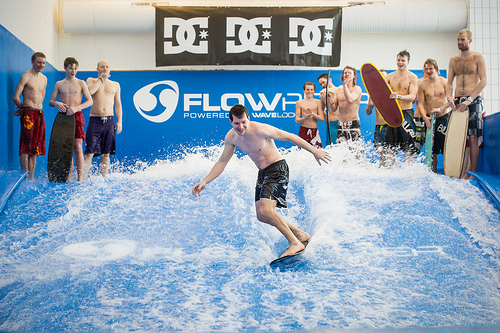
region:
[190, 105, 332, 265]
A person surfing indoors.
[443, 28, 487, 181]
A man with a tan surfboard.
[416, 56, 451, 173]
A person with a green surfboard.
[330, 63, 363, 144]
A male in black and white shorts.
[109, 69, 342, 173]
A blue and white sign.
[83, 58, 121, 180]
A guy wearing blue shorts.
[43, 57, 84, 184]
A kid with a black surfboard.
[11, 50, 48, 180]
A person wearing red shorts.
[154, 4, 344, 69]
A black and white sign.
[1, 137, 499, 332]
A indoor surf simulator.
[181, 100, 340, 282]
surfer at an indoor wave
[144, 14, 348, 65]
banner on a wall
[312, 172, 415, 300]
imitation wave on a ramp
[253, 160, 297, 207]
swim trunks on a surfer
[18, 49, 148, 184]
boys waiting to surf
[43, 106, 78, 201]
surfboard in boy's hands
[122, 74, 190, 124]
design on back wall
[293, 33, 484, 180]
crowd of males watching surfer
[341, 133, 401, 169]
water splashing from waves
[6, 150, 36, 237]
side of indoor wave ramp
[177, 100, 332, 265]
Man surfing surfing on a blue tarp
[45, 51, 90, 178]
Young man holding a surfboard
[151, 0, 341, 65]
Black and white banner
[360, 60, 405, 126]
Red and yellow surfboard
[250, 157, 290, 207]
Navy blue swim trunks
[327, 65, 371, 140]
Young man cheering at surfer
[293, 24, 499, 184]
Group of young men in swim trunks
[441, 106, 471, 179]
Tan and brown surfboard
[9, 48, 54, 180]
Young man leaning against a wall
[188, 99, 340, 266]
Man surfing on water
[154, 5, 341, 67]
Black DC banner on the wall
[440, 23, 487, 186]
Man holding surf board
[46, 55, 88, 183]
Boy holding surf board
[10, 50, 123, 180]
Group of guys watching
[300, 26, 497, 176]
Group of guys spectating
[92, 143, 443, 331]
Rushing water making waves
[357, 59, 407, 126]
Red and yellow surf board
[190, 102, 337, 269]
Man wearing black swim trunks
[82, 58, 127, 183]
man wearing blue surf trunks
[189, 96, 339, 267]
man in wave pool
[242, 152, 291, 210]
black shorts on the man in wave pool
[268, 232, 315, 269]
small surf board of the man in wave pool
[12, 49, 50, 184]
young man in red shorts at edge of wave pool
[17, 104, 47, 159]
red shorts on young man at edge of wave pool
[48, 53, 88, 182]
young man in red shorts holding small surfboard at edge of wave pool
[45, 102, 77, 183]
small surf board of the young man in red shorts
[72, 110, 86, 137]
red shorts of the young man standing with small board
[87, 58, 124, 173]
young man in blue shorts standing at edge of wave pool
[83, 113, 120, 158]
young mans blue shorts